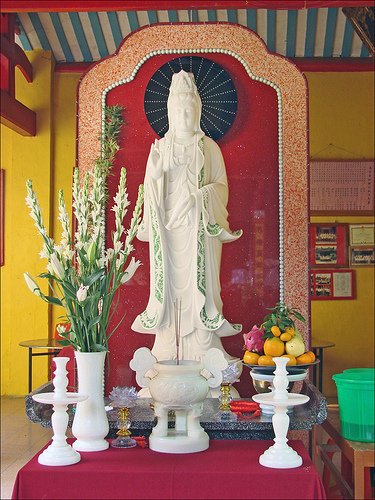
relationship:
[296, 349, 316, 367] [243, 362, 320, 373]
fruit in bowl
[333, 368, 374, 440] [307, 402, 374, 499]
tub on table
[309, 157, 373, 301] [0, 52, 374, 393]
pictures are on wall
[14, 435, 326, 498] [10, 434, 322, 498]
cloth on table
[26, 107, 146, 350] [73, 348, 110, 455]
flowers are in vase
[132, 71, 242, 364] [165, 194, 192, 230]
someone holding frisbee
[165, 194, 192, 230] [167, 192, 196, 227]
frisbee in hands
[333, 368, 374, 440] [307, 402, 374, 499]
bucket on table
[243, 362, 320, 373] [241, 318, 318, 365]
bowl of fruit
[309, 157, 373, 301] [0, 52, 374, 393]
pictures hanging on wall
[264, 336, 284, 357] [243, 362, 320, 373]
orange in bowl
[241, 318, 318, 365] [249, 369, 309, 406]
fruit on pedestal